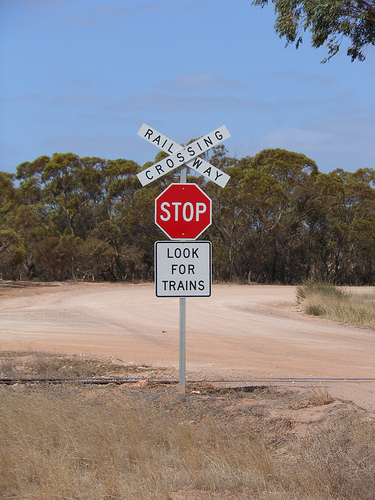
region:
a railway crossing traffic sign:
[130, 118, 238, 195]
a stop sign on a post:
[142, 174, 222, 239]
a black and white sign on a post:
[144, 235, 208, 301]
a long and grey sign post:
[173, 269, 193, 389]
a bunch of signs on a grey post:
[138, 104, 209, 395]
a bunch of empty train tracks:
[16, 360, 162, 409]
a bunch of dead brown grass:
[105, 403, 206, 483]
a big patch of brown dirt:
[88, 307, 159, 355]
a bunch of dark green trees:
[241, 176, 357, 266]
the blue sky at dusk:
[57, 95, 142, 148]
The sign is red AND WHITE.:
[153, 179, 214, 240]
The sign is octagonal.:
[147, 180, 218, 240]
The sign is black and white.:
[150, 239, 217, 300]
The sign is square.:
[152, 237, 214, 299]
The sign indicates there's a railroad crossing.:
[128, 116, 236, 191]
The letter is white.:
[159, 198, 171, 221]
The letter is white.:
[169, 195, 182, 224]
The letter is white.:
[179, 196, 196, 224]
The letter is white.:
[192, 198, 205, 229]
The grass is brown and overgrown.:
[0, 384, 374, 499]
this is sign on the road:
[129, 110, 236, 183]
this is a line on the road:
[148, 182, 232, 242]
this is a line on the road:
[140, 239, 236, 317]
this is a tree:
[6, 189, 64, 251]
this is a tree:
[64, 192, 118, 276]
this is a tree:
[217, 188, 249, 283]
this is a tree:
[271, 188, 316, 288]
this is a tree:
[309, 188, 372, 283]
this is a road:
[33, 280, 166, 361]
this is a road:
[227, 294, 308, 373]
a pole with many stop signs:
[146, 107, 206, 394]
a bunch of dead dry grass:
[51, 448, 106, 489]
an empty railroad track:
[38, 362, 76, 394]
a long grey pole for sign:
[171, 301, 205, 421]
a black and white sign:
[141, 235, 214, 307]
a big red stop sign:
[148, 179, 216, 242]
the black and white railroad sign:
[116, 119, 241, 191]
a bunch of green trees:
[26, 165, 111, 260]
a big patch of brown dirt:
[88, 277, 143, 345]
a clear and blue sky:
[29, 109, 108, 149]